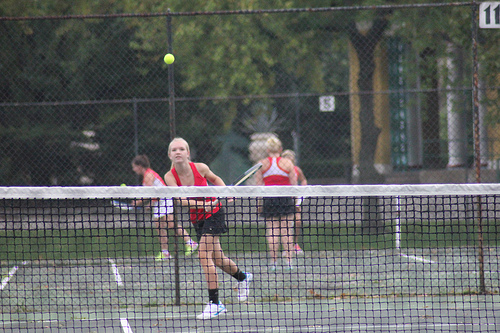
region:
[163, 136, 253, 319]
A girl in red playing tennis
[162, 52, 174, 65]
A tennis ball that was hit by the girl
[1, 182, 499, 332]
A white and black tennis net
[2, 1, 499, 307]
A tall fence separating tennis courts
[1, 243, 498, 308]
Another tennis court beyond the fence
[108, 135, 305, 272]
A group of girls playing in the other court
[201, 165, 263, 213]
A short, dark tennis racket held by the girl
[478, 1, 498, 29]
A number label on the tennis court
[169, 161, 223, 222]
A red athletic tank top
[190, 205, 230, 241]
Black athletic shorts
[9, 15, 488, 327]
the game is tennis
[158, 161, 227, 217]
the top is red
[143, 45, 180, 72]
the ball is in the air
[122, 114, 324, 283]
the people are four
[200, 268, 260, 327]
the shoes are white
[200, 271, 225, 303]
the socks are black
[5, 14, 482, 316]
the sport is outside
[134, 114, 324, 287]
the sport is being played by girls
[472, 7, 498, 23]
number 11 can be seen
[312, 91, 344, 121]
number 5 can be seen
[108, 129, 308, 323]
people are playing tennis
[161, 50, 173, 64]
tennis ball is light green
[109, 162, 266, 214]
people are holding tennis rackets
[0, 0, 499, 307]
large chain link fences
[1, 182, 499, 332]
net between sides of tennis court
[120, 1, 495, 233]
large tree behind fence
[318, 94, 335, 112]
white tag above back court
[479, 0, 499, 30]
white tag above closest court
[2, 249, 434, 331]
white lines on courts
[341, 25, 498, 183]
several columns behind tree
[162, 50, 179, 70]
green tennis ball in air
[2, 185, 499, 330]
tennis net on court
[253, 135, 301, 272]
woman standing on tennis court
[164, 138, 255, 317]
female playing a game of tennis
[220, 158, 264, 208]
tennis racket in woman's hand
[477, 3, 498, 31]
white sign on fence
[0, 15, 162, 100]
black fence around the court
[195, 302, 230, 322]
white tennis shoe on left foot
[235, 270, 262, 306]
white tennis shoe on right foot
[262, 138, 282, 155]
the woman's blonde hair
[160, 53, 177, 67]
a small green tennis ball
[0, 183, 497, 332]
a long tennis net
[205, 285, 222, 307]
a woman's black sock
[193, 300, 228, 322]
a woman's white shoe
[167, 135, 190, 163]
the head of a girl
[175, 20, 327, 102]
green tree leaves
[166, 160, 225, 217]
a woman's red tank top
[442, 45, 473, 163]
a tall gray pole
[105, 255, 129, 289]
a long white pole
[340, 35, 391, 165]
a brown building column